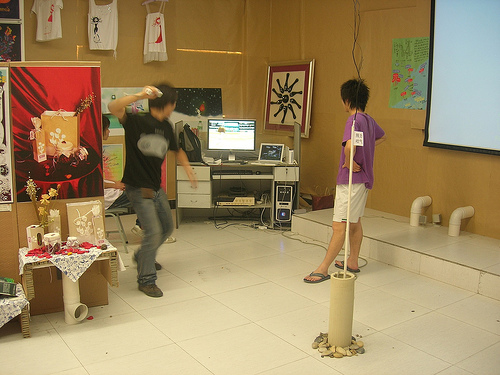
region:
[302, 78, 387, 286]
A person wearing white shorts, purple tshirt and sandals.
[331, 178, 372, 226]
white shorts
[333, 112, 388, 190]
purple tshirt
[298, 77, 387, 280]
A person standing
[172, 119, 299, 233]
a computer desk with equipment and a black backpack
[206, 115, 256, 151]
a computer screen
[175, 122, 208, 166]
black and gray backpack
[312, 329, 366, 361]
rocks in a circle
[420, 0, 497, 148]
white screen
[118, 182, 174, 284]
blue jeans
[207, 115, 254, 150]
a good sized computer screen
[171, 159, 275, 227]
a desk with three drawers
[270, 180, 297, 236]
a desktop PC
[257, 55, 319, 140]
a picture with ten points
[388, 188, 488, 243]
two plastic pipes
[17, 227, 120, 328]
a table made with a plastic pipe as a leg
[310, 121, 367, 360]
free standing piece of folk art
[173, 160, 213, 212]
three drawers with the top one open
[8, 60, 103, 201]
a painting of still life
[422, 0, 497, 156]
a whiteboard on the right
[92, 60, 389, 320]
people engaging with electronic game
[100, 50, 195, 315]
man lifting arm and twisting body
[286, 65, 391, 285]
person with hand on waist watching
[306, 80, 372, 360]
white pole in tube surrounded by rocks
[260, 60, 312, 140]
picture of black objects swirling in circle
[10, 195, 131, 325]
pipe supporting table holding tan objects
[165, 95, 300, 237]
table with monitor and other electronics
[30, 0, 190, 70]
white garments hanging against wall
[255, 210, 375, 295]
feet wearing sandals pointed in different directions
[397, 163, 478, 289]
pipes on platform connected to wall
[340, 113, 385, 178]
the shirt is white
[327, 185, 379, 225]
the short is white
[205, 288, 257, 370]
the tiles are white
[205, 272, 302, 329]
the tiles are square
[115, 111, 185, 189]
the shirt is black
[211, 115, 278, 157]
the monitor is on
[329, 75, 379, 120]
the hair is black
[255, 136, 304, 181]
the laptop is on the table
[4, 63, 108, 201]
the picture has a red background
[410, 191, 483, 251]
there are pipes coming from the wall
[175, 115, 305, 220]
A computer desk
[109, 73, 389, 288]
two people watching a tv screen.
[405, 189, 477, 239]
two white piping's coming out the wall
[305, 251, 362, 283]
a pair of flip flops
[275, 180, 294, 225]
a computer tower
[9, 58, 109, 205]
a painting hanging up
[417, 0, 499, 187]
a pull down screen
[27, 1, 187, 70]
Three white shirts hanging on the wall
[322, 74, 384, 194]
a person with there hands on there hips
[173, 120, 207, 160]
a grey and black backpack